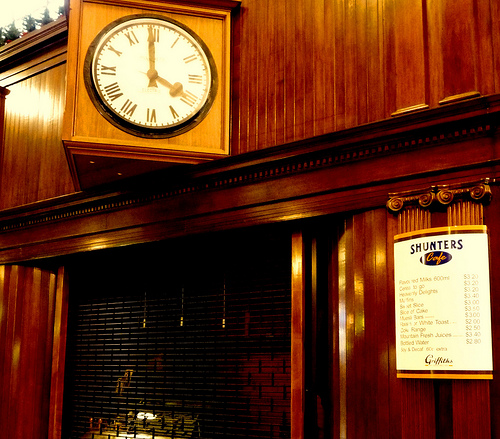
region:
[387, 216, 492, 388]
a white menu on the wall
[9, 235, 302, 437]
a metal gate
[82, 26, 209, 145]
a clock on the wall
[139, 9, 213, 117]
hands of the clock on the wall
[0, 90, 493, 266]
ledge of the wall with the clock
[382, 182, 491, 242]
design on the walls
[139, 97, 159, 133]
roman numeral six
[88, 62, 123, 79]
roman numeral nine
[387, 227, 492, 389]
white piece of paper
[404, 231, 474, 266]
name of the restaurant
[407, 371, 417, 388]
the line is yellow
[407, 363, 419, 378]
the line is yellow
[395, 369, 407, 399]
the line is yellow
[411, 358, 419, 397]
the line is yellow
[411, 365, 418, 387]
the line is yellow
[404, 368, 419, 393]
the line is yellow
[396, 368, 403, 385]
the line is yellow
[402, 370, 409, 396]
the line is yellow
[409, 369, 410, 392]
the line is yellow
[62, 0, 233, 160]
The clock says it is 4 PM.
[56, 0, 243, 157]
The clock is black and white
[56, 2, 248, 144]
The clock is on wood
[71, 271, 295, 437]
The fireplace is closed off.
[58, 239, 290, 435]
A black metal grate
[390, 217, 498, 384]
A menu for Shunters Cafe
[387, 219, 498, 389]
The menu is on the wall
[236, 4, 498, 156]
The walls are made of wood.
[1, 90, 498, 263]
The mantle is empty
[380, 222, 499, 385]
The menu is laminated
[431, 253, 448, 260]
word cafe is written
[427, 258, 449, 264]
word cafe is written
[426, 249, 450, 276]
word cafe is written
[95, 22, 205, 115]
this is a clock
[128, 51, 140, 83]
the clock is white in color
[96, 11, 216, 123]
the frame is round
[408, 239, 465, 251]
this is a writing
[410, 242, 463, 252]
the writing is in black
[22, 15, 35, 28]
the tree has green leaves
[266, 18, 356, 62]
this is a wall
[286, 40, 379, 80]
the wall is wooden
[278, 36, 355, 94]
the wall is brown in color